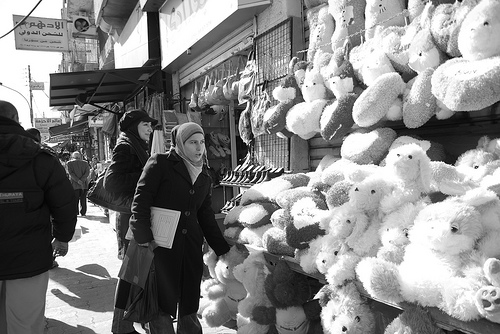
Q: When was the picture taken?
A: Daytime.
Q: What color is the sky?
A: White.